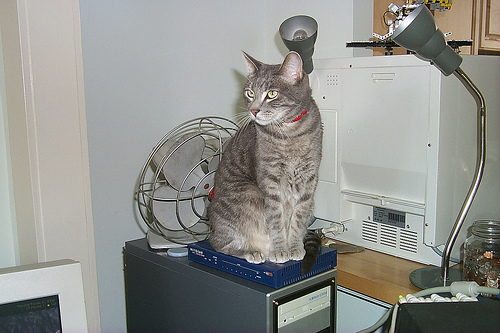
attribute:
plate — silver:
[368, 203, 404, 230]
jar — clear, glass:
[456, 216, 498, 293]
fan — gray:
[133, 116, 240, 246]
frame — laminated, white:
[3, 255, 98, 330]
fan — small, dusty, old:
[129, 110, 217, 247]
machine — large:
[298, 49, 498, 260]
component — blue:
[187, 238, 337, 289]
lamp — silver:
[375, 3, 483, 295]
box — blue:
[181, 253, 343, 290]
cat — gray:
[206, 44, 321, 272]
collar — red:
[288, 109, 313, 121]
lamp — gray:
[277, 14, 318, 74]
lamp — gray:
[388, 2, 488, 289]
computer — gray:
[118, 218, 340, 331]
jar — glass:
[459, 218, 498, 286]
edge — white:
[0, 251, 89, 275]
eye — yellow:
[265, 86, 279, 105]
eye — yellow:
[243, 89, 258, 99]